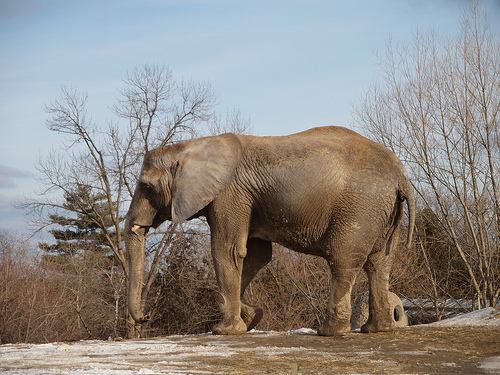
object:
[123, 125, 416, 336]
elephant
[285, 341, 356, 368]
grass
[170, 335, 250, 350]
dirt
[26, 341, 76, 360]
dirt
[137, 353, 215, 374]
dirt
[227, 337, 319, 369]
dirt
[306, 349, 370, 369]
dirt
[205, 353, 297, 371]
dirt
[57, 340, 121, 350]
dirt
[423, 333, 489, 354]
dirt patch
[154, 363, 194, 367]
dirt patch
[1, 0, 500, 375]
outside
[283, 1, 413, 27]
daytime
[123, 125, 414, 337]
animal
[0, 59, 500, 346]
background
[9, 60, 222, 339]
tree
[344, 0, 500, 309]
tree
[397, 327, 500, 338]
dirt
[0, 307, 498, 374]
ground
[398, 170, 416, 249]
tail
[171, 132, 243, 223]
ear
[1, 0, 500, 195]
sky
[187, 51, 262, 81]
cloud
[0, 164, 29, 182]
cloud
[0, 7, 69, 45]
cloud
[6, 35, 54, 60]
cloud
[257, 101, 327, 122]
cloud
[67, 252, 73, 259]
branch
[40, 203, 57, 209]
branch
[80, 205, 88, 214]
branch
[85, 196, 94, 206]
branch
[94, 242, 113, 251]
branch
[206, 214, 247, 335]
leg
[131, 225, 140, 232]
tusk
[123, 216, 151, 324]
trunk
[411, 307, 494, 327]
hill